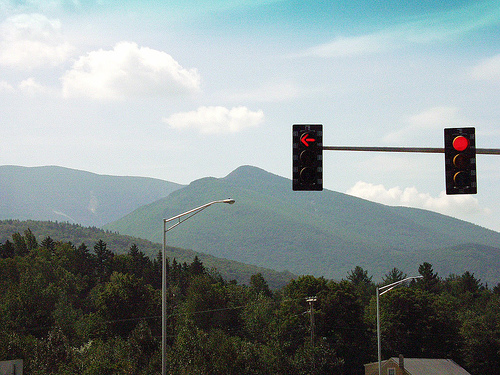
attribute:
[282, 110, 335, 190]
light — red, traffic, black, metal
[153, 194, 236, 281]
pole — metal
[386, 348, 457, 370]
house — yellow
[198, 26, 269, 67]
sky — blue, cloudy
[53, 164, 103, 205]
mountian — far, green